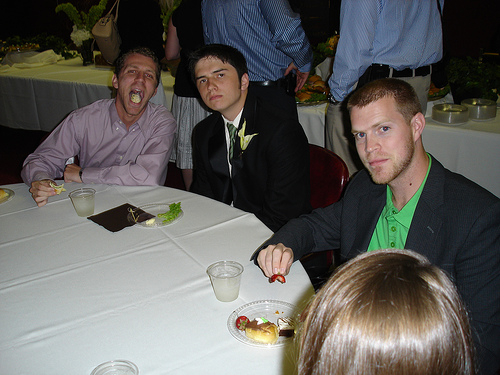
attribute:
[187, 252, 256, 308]
cup — plastic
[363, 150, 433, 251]
shirt — green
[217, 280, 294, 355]
plate — serving plate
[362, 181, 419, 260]
shirt — green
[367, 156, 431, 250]
shirt — polo shirt, light green